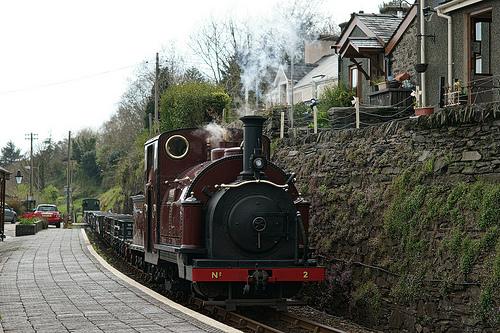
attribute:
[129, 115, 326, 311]
train engine — old fashioned, burgundy black, red, steam powered, black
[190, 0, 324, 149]
smoke — white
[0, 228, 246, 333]
platform — stone, gray, lined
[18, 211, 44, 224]
flowers — red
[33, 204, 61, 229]
car — red, parked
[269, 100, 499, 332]
wall — stone, rocky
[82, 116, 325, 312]
train — vintage, moving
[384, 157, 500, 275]
plants — green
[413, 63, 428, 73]
flower pot — hanging, black, empty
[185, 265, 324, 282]
front bumper — red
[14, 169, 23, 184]
street light — vintage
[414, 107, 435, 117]
flower pot — clay, red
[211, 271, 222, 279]
word no — gold, yellow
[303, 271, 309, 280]
number 2 — gold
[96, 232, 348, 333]
train tracks — long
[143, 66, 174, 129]
tree — far away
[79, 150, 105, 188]
tree — far away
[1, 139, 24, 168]
tree — far away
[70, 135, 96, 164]
tree — far away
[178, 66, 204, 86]
tree — far away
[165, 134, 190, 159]
window — large, silver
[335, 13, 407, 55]
roof — triangular